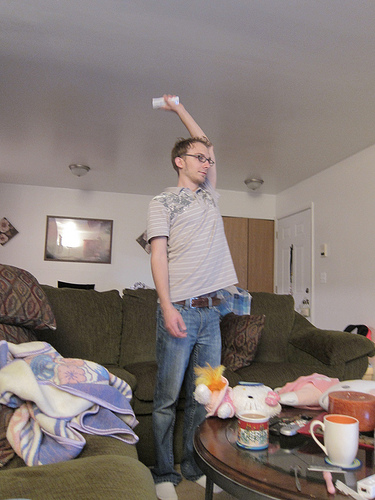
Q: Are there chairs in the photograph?
A: No, there are no chairs.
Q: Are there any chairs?
A: No, there are no chairs.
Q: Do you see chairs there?
A: No, there are no chairs.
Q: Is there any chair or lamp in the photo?
A: No, there are no chairs or lamps.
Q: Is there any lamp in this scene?
A: No, there are no lamps.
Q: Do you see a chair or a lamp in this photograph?
A: No, there are no lamps or chairs.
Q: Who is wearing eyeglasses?
A: The man is wearing eyeglasses.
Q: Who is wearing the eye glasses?
A: The man is wearing eyeglasses.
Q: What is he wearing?
A: The man is wearing eye glasses.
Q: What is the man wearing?
A: The man is wearing eye glasses.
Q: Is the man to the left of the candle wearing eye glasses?
A: Yes, the man is wearing eye glasses.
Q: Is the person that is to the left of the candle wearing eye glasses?
A: Yes, the man is wearing eye glasses.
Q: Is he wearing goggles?
A: No, the man is wearing eye glasses.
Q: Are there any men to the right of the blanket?
A: Yes, there is a man to the right of the blanket.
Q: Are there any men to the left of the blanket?
A: No, the man is to the right of the blanket.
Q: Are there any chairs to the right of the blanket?
A: No, there is a man to the right of the blanket.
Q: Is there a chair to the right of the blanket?
A: No, there is a man to the right of the blanket.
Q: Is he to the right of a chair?
A: No, the man is to the right of the blanket.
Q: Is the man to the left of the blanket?
A: No, the man is to the right of the blanket.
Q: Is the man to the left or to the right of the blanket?
A: The man is to the right of the blanket.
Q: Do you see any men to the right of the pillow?
A: Yes, there is a man to the right of the pillow.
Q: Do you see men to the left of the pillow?
A: No, the man is to the right of the pillow.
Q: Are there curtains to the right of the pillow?
A: No, there is a man to the right of the pillow.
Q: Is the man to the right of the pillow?
A: Yes, the man is to the right of the pillow.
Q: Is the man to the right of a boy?
A: No, the man is to the right of the pillow.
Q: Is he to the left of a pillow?
A: No, the man is to the right of a pillow.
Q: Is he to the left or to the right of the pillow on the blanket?
A: The man is to the right of the pillow.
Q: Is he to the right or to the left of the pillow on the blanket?
A: The man is to the right of the pillow.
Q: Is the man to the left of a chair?
A: No, the man is to the left of the candle.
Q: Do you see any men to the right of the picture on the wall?
A: Yes, there is a man to the right of the picture.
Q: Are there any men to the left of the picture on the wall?
A: No, the man is to the right of the picture.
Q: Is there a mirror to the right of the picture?
A: No, there is a man to the right of the picture.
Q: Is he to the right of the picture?
A: Yes, the man is to the right of the picture.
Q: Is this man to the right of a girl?
A: No, the man is to the right of the picture.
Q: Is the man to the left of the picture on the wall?
A: No, the man is to the right of the picture.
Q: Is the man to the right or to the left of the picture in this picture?
A: The man is to the right of the picture.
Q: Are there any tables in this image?
A: Yes, there is a table.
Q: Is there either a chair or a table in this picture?
A: Yes, there is a table.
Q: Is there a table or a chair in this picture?
A: Yes, there is a table.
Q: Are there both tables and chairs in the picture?
A: No, there is a table but no chairs.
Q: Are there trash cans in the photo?
A: No, there are no trash cans.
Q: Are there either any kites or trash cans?
A: No, there are no trash cans or kites.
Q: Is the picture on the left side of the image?
A: Yes, the picture is on the left of the image.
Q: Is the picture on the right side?
A: No, the picture is on the left of the image.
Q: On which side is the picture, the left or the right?
A: The picture is on the left of the image.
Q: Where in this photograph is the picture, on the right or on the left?
A: The picture is on the left of the image.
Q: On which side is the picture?
A: The picture is on the left of the image.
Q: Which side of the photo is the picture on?
A: The picture is on the left of the image.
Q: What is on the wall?
A: The picture is on the wall.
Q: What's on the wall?
A: The picture is on the wall.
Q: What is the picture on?
A: The picture is on the wall.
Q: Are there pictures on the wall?
A: Yes, there is a picture on the wall.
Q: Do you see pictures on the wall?
A: Yes, there is a picture on the wall.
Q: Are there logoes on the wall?
A: No, there is a picture on the wall.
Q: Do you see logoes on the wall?
A: No, there is a picture on the wall.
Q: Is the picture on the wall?
A: Yes, the picture is on the wall.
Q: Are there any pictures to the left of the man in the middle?
A: Yes, there is a picture to the left of the man.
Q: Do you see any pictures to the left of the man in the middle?
A: Yes, there is a picture to the left of the man.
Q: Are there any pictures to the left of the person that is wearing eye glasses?
A: Yes, there is a picture to the left of the man.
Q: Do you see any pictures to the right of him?
A: No, the picture is to the left of the man.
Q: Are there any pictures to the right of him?
A: No, the picture is to the left of the man.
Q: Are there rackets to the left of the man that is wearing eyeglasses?
A: No, there is a picture to the left of the man.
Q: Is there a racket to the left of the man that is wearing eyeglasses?
A: No, there is a picture to the left of the man.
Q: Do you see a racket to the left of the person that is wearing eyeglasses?
A: No, there is a picture to the left of the man.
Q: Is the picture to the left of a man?
A: Yes, the picture is to the left of a man.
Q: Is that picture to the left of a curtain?
A: No, the picture is to the left of a man.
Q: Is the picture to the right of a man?
A: No, the picture is to the left of a man.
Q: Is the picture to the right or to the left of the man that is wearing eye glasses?
A: The picture is to the left of the man.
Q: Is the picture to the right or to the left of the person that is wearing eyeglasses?
A: The picture is to the left of the man.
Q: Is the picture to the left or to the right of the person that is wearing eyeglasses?
A: The picture is to the left of the man.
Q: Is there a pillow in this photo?
A: Yes, there is a pillow.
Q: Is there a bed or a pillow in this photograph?
A: Yes, there is a pillow.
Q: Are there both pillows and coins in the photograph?
A: No, there is a pillow but no coins.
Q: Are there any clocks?
A: No, there are no clocks.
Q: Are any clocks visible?
A: No, there are no clocks.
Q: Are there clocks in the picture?
A: No, there are no clocks.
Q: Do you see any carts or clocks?
A: No, there are no clocks or carts.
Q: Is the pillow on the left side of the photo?
A: Yes, the pillow is on the left of the image.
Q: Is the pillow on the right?
A: No, the pillow is on the left of the image.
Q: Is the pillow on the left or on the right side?
A: The pillow is on the left of the image.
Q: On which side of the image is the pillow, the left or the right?
A: The pillow is on the left of the image.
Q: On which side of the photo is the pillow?
A: The pillow is on the left of the image.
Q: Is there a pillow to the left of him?
A: Yes, there is a pillow to the left of the man.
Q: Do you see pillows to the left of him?
A: Yes, there is a pillow to the left of the man.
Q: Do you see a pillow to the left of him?
A: Yes, there is a pillow to the left of the man.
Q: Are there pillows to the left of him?
A: Yes, there is a pillow to the left of the man.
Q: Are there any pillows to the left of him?
A: Yes, there is a pillow to the left of the man.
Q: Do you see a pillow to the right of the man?
A: No, the pillow is to the left of the man.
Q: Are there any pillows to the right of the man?
A: No, the pillow is to the left of the man.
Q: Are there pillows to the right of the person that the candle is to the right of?
A: No, the pillow is to the left of the man.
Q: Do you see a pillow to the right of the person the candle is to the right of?
A: No, the pillow is to the left of the man.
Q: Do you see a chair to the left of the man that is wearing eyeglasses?
A: No, there is a pillow to the left of the man.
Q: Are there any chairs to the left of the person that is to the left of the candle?
A: No, there is a pillow to the left of the man.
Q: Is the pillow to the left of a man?
A: Yes, the pillow is to the left of a man.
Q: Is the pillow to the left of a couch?
A: No, the pillow is to the left of a man.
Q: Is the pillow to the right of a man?
A: No, the pillow is to the left of a man.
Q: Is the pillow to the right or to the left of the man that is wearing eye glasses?
A: The pillow is to the left of the man.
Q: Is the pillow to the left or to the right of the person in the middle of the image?
A: The pillow is to the left of the man.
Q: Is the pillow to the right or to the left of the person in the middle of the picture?
A: The pillow is to the left of the man.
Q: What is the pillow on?
A: The pillow is on the blanket.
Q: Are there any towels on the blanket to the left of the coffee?
A: No, there is a pillow on the blanket.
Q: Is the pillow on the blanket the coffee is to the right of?
A: Yes, the pillow is on the blanket.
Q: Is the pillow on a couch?
A: No, the pillow is on the blanket.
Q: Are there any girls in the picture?
A: No, there are no girls.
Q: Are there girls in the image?
A: No, there are no girls.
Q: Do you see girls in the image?
A: No, there are no girls.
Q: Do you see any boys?
A: No, there are no boys.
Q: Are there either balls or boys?
A: No, there are no boys or balls.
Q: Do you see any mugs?
A: Yes, there is a mug.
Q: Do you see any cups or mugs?
A: Yes, there is a mug.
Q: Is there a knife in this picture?
A: No, there are no knives.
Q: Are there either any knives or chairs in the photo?
A: No, there are no knives or chairs.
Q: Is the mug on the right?
A: Yes, the mug is on the right of the image.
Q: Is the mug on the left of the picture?
A: No, the mug is on the right of the image.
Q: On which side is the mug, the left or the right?
A: The mug is on the right of the image.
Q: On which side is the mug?
A: The mug is on the right of the image.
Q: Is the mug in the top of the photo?
A: No, the mug is in the bottom of the image.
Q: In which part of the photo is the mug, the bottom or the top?
A: The mug is in the bottom of the image.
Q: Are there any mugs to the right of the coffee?
A: Yes, there is a mug to the right of the coffee.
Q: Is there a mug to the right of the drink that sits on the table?
A: Yes, there is a mug to the right of the coffee.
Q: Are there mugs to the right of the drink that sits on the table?
A: Yes, there is a mug to the right of the coffee.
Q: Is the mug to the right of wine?
A: No, the mug is to the right of the coffee.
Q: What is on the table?
A: The mug is on the table.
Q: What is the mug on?
A: The mug is on the table.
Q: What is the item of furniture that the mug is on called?
A: The piece of furniture is a table.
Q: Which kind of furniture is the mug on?
A: The mug is on the table.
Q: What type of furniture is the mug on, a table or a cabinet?
A: The mug is on a table.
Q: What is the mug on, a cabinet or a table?
A: The mug is on a table.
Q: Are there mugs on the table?
A: Yes, there is a mug on the table.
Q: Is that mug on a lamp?
A: No, the mug is on a table.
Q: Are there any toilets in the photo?
A: No, there are no toilets.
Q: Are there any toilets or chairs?
A: No, there are no toilets or chairs.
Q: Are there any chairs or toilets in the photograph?
A: No, there are no toilets or chairs.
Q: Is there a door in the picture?
A: Yes, there is a door.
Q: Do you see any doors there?
A: Yes, there is a door.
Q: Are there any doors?
A: Yes, there is a door.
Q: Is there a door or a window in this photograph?
A: Yes, there is a door.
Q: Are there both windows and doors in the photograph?
A: No, there is a door but no windows.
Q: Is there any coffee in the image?
A: Yes, there is coffee.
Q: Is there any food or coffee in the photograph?
A: Yes, there is coffee.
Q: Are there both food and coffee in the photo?
A: No, there is coffee but no food.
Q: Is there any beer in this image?
A: No, there is no beer.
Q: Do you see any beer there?
A: No, there is no beer.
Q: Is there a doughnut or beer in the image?
A: No, there are no beer or donuts.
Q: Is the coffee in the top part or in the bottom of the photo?
A: The coffee is in the bottom of the image.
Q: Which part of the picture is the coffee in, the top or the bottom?
A: The coffee is in the bottom of the image.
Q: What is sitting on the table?
A: The coffee is sitting on the table.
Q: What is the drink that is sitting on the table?
A: The drink is coffee.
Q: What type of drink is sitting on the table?
A: The drink is coffee.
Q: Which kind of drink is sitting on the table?
A: The drink is coffee.